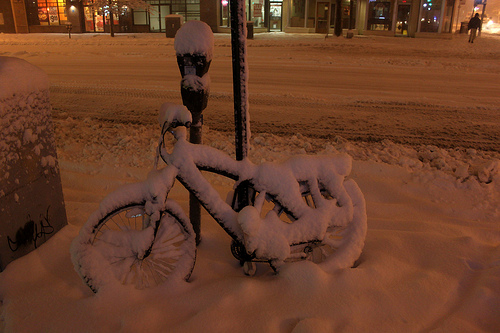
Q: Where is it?
A: This is at the street.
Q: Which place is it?
A: It is a street.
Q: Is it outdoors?
A: Yes, it is outdoors.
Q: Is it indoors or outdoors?
A: It is outdoors.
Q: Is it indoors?
A: No, it is outdoors.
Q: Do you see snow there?
A: Yes, there is snow.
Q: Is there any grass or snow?
A: Yes, there is snow.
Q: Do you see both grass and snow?
A: No, there is snow but no grass.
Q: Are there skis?
A: No, there are no skis.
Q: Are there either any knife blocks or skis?
A: No, there are no skis or knife blocks.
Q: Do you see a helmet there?
A: No, there are no helmets.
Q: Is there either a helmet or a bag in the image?
A: No, there are no helmets or bags.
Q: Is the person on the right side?
A: Yes, the person is on the right of the image.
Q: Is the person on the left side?
A: No, the person is on the right of the image.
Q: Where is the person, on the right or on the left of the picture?
A: The person is on the right of the image.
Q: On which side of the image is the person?
A: The person is on the right of the image.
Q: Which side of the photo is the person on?
A: The person is on the right of the image.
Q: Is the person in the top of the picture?
A: Yes, the person is in the top of the image.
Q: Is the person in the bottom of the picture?
A: No, the person is in the top of the image.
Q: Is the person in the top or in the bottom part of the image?
A: The person is in the top of the image.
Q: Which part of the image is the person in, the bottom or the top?
A: The person is in the top of the image.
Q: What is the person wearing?
A: The person is wearing shoes.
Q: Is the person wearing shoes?
A: Yes, the person is wearing shoes.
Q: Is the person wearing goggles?
A: No, the person is wearing shoes.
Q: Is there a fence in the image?
A: No, there are no fences.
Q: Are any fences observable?
A: No, there are no fences.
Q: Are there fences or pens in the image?
A: No, there are no fences or pens.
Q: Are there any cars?
A: No, there are no cars.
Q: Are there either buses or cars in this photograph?
A: No, there are no cars or buses.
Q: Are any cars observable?
A: No, there are no cars.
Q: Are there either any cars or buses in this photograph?
A: No, there are no cars or buses.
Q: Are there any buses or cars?
A: No, there are no cars or buses.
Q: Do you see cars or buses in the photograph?
A: No, there are no cars or buses.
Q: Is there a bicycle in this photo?
A: Yes, there is a bicycle.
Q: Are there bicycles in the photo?
A: Yes, there is a bicycle.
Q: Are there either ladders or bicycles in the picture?
A: Yes, there is a bicycle.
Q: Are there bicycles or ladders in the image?
A: Yes, there is a bicycle.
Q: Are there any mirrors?
A: No, there are no mirrors.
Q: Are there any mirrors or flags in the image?
A: No, there are no mirrors or flags.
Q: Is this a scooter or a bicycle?
A: This is a bicycle.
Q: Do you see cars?
A: No, there are no cars.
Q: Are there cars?
A: No, there are no cars.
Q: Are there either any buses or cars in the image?
A: No, there are no cars or buses.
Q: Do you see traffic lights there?
A: No, there are no traffic lights.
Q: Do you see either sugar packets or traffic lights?
A: No, there are no traffic lights or sugar packets.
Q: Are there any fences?
A: No, there are no fences.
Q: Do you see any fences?
A: No, there are no fences.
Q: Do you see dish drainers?
A: No, there are no dish drainers.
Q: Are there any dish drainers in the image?
A: No, there are no dish drainers.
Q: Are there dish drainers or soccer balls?
A: No, there are no dish drainers or soccer balls.